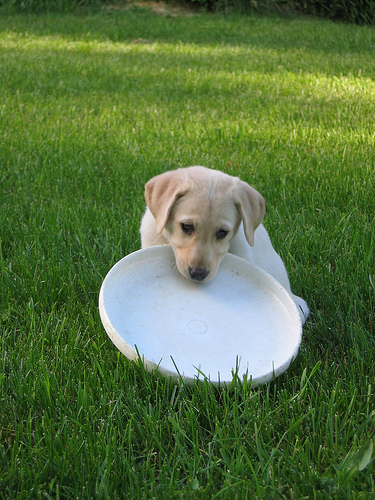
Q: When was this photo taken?
A: Daytime.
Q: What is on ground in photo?
A: Grass.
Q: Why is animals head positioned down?
A: To hold object.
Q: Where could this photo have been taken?
A: Backyard.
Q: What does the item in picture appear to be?
A: Frisbee.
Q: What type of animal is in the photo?
A: Dog.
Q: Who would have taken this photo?
A: Dog's owner.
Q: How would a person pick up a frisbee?
A: With hands.